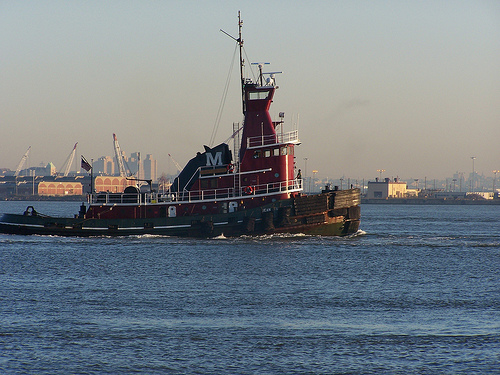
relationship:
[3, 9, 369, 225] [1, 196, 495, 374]
ship in ocean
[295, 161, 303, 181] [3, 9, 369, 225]
person on ship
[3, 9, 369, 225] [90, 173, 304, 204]
ship has rails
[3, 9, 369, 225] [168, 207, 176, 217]
ship has door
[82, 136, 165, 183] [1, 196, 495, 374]
buildings behind ocean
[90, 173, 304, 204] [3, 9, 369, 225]
rails on ship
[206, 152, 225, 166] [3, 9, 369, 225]
m on ship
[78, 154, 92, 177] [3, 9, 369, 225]
flag on ship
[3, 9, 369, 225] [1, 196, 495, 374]
ship on ocean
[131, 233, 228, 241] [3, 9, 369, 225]
foam under ship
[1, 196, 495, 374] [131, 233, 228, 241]
ocean has foam